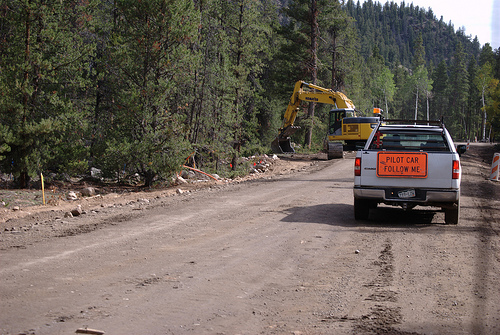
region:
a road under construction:
[0, 219, 473, 303]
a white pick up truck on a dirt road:
[243, 82, 478, 322]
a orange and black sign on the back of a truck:
[376, 142, 431, 199]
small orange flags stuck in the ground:
[221, 151, 285, 183]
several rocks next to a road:
[0, 184, 205, 249]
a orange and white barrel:
[491, 144, 497, 193]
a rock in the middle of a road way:
[328, 241, 370, 280]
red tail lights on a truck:
[351, 156, 466, 181]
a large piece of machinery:
[264, 79, 379, 162]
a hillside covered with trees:
[345, 19, 468, 84]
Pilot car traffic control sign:
[374, 151, 430, 181]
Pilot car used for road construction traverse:
[346, 116, 463, 227]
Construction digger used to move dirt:
[270, 77, 380, 162]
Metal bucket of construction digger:
[270, 124, 307, 158]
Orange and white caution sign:
[486, 146, 498, 187]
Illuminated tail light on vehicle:
[349, 155, 364, 177]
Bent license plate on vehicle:
[389, 183, 423, 203]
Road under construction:
[3, 136, 495, 331]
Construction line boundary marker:
[35, 170, 53, 206]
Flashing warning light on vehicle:
[368, 104, 382, 119]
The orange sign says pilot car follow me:
[375, 154, 424, 174]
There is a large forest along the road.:
[30, 0, 280, 202]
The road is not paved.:
[122, 205, 492, 317]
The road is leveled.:
[77, 188, 448, 333]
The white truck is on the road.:
[353, 121, 465, 222]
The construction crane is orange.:
[273, 75, 385, 150]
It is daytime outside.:
[427, 0, 495, 47]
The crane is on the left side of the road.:
[257, 78, 467, 162]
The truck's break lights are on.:
[351, 139, 461, 219]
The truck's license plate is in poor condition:
[387, 185, 422, 201]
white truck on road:
[353, 120, 461, 222]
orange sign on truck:
[376, 153, 428, 179]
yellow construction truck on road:
[269, 79, 379, 154]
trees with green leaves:
[1, 1, 361, 178]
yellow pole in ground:
[40, 171, 45, 206]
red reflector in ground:
[228, 160, 233, 167]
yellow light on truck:
[374, 105, 381, 113]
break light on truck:
[354, 158, 361, 177]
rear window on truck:
[369, 129, 448, 154]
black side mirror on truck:
[458, 144, 468, 152]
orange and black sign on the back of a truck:
[373, 148, 430, 182]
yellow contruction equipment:
[275, 63, 378, 156]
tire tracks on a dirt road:
[325, 240, 415, 334]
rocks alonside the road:
[55, 183, 167, 215]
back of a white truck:
[338, 99, 474, 234]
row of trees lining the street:
[27, 35, 263, 193]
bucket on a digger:
[267, 120, 302, 155]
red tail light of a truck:
[354, 158, 362, 173]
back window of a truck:
[374, 122, 445, 156]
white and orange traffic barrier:
[487, 145, 498, 189]